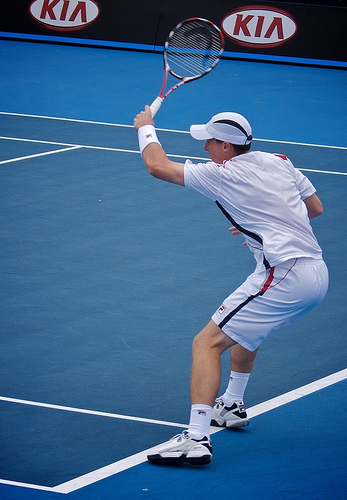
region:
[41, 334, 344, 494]
Boundary line at the end of a tennis court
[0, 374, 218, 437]
Minor boundary line on the court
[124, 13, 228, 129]
Tennis racket in the man's left hand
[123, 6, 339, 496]
Tennis player waiting to return the ball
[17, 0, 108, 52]
Advertisement for an auto maker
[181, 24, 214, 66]
Logo on the tennis racket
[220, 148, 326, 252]
Right hand without a tennis racket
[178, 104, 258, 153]
The tennis player's cap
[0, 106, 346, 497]
Playable area of the tennis court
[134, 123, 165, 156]
Wristband for absorbing the man's sweat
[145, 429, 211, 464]
A white and black tennis shoe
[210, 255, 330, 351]
A white pair of shorts with a black and red stripe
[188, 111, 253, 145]
A white and black hat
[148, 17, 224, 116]
A red, black and white tennis racket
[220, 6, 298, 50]
A Kia logo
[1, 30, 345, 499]
A blue tennis court with white lines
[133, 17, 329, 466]
A man holding a tennis racket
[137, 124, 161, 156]
A white armband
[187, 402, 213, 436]
A white sock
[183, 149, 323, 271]
A white shirt with a black stripe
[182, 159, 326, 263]
white shirt on man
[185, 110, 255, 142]
white hat on man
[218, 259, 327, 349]
white shorts on man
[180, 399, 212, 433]
white left sock of man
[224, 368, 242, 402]
white right sock of man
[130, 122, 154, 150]
white wrist band of man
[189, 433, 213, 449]
black part of shoe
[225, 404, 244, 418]
black part of shoe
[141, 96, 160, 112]
white handle of racket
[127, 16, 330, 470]
man holding tennis racket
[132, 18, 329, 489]
a tennis player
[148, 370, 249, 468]
white and black shoes with white socks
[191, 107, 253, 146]
man wearing a white cap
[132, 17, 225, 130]
man holding a tennis racket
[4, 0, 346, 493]
man playing tennis on a tennis court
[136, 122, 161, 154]
man wearing a white wristband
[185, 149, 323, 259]
man wearing a white shirt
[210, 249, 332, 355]
white shorts with blue and red lines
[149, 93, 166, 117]
white handle of a tennis racket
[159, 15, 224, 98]
a red and black tennis racket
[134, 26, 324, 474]
man on tennis court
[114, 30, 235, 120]
man holding tennis racket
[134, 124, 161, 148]
sleeve on left wrist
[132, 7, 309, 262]
man holding racket with left hand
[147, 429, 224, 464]
black and white tennis shoes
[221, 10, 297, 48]
"kia" sign on wall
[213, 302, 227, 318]
logo on shorts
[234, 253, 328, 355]
white tennis shorts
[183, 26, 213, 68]
logo on tennis racket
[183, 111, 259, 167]
man wearing white hat